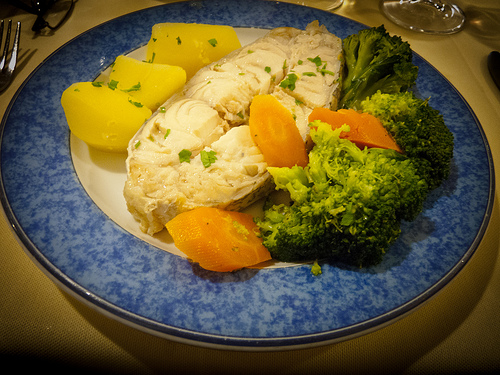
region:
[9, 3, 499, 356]
this is a dinner plate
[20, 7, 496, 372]
blue trim on plate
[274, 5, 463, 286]
broccoli spears on plate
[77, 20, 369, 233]
white fish on plate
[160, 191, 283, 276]
orange veggies on plate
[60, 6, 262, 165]
yellow veggies on plate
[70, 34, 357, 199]
green herbs on food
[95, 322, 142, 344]
shadow under the plate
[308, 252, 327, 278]
tiny crumb on side of plate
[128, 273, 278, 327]
beautiful blue color on plate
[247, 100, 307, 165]
slice of orange carrot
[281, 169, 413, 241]
stalk of green broccoli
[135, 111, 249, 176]
big piece of fish on plate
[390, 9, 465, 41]
base of clear glass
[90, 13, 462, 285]
plate filled with food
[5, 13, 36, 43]
end of red fork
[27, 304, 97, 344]
brown covering on the surface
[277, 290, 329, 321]
the plate is blue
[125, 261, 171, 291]
the blue plate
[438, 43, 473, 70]
a table cloth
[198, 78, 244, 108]
meat on the plate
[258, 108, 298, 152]
the carrot on the plate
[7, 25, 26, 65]
a fork on the table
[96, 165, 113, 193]
the center of the plate is white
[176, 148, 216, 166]
green chives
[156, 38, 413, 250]
food on the plate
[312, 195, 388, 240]
the brocoli is green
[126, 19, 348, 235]
poached fish on top of a plate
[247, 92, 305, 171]
carrot on top of fish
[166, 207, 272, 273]
carrot next to fish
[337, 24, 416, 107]
broccoli floret on top of the plate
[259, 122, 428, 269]
steamed broccoli next to carrot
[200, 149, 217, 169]
parsley flake on top of fish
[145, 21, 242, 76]
yellow potato wedge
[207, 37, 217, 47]
green parsley flake on top of potato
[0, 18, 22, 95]
fork to the left of the plate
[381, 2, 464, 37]
glass above plate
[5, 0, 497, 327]
round blue plate of fish and vegetables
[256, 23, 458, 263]
green cooked broccoli on blue plate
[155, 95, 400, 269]
cooked sliced carrots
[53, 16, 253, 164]
three white boiled potatoes with green parsley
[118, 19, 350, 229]
large piece of cooked white fish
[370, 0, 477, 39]
bottom of clear drinking glass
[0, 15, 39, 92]
edge of silver fork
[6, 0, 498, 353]
yellow placemat under dish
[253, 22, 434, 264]
green broccoli florets on plate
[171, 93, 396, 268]
sliced carrots cooked with broccoli